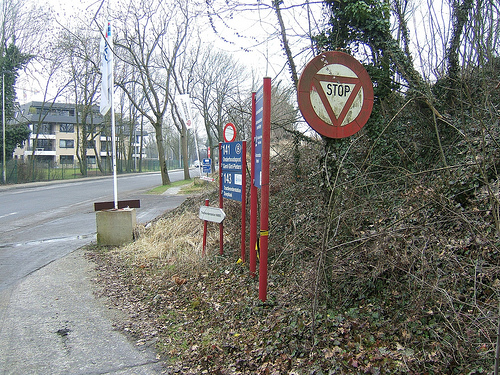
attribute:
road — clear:
[4, 161, 170, 277]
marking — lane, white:
[0, 210, 17, 219]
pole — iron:
[257, 76, 275, 306]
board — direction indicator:
[198, 194, 231, 237]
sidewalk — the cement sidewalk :
[12, 275, 122, 371]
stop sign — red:
[297, 44, 382, 151]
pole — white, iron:
[103, 0, 120, 210]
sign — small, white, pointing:
[190, 201, 238, 236]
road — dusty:
[13, 177, 165, 244]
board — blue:
[195, 151, 290, 215]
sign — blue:
[247, 88, 281, 194]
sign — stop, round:
[294, 42, 376, 142]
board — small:
[196, 204, 233, 228]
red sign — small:
[208, 119, 243, 149]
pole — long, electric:
[88, 15, 130, 210]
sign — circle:
[291, 48, 375, 140]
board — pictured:
[205, 90, 285, 284]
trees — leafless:
[11, 1, 227, 95]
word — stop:
[326, 82, 351, 97]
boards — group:
[211, 89, 267, 281]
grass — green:
[107, 70, 496, 373]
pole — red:
[257, 74, 272, 304]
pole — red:
[247, 90, 257, 275]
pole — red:
[235, 137, 251, 263]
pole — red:
[218, 137, 224, 253]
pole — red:
[199, 194, 209, 252]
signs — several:
[198, 49, 384, 294]